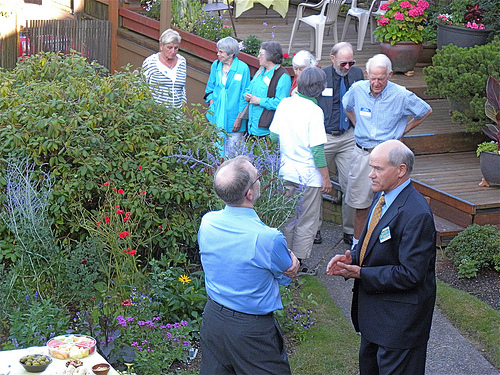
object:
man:
[341, 51, 431, 146]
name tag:
[355, 105, 376, 121]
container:
[45, 332, 97, 359]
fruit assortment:
[50, 332, 96, 349]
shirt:
[196, 206, 293, 314]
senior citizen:
[142, 25, 193, 109]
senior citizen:
[203, 32, 253, 147]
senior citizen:
[264, 65, 340, 278]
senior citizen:
[250, 33, 293, 135]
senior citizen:
[342, 37, 433, 266]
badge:
[376, 221, 395, 243]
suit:
[351, 184, 451, 374]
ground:
[425, 131, 465, 166]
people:
[125, 24, 192, 120]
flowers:
[378, 0, 432, 28]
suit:
[303, 186, 477, 374]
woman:
[144, 15, 190, 130]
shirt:
[140, 55, 192, 106]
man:
[307, 137, 459, 355]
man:
[337, 48, 434, 257]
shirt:
[335, 75, 432, 150]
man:
[340, 139, 427, 373]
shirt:
[195, 204, 298, 315]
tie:
[355, 201, 390, 271]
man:
[185, 160, 305, 373]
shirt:
[198, 204, 291, 307]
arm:
[273, 222, 300, 282]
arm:
[262, 240, 295, 285]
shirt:
[270, 94, 326, 192]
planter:
[373, 36, 425, 69]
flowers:
[372, 0, 431, 38]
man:
[363, 136, 426, 223]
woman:
[121, 20, 206, 120]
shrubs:
[2, 68, 211, 329]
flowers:
[4, 149, 199, 361]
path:
[433, 328, 483, 368]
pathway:
[306, 223, 496, 374]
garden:
[0, 47, 295, 371]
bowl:
[18, 353, 49, 374]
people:
[200, 149, 300, 367]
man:
[329, 139, 439, 374]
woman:
[266, 65, 338, 281]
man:
[198, 156, 305, 372]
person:
[279, 65, 336, 279]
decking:
[402, 144, 500, 252]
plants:
[471, 136, 499, 155]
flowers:
[102, 274, 219, 359]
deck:
[409, 166, 490, 219]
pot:
[382, 42, 432, 73]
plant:
[375, 9, 426, 42]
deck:
[394, 71, 448, 100]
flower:
[394, 12, 401, 21]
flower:
[378, 17, 391, 28]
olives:
[23, 338, 53, 371]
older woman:
[203, 37, 253, 145]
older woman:
[139, 30, 189, 105]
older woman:
[244, 40, 296, 162]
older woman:
[289, 50, 318, 83]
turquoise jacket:
[206, 58, 252, 136]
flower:
[170, 262, 190, 288]